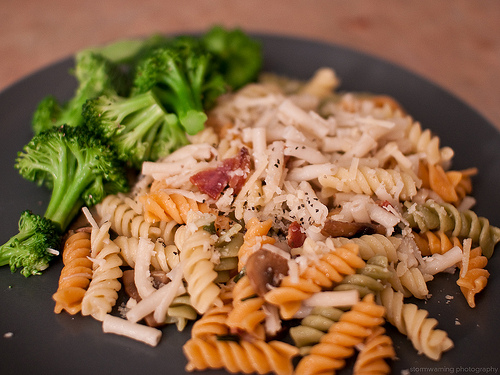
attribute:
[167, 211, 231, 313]
rotini pasta —  of rotini,  off-white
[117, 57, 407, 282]
salad —  of pasta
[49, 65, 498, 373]
pasta —  orange,  of rotini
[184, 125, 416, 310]
pasta —  multi-colored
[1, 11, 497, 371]
plate —  black,  round